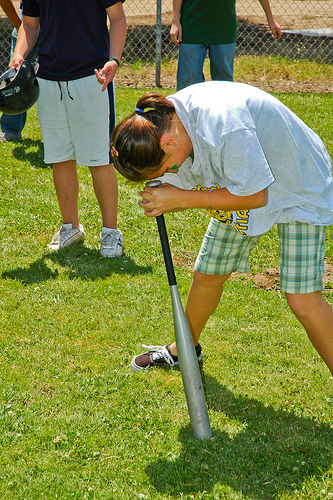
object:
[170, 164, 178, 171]
paint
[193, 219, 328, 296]
shorts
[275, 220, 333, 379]
legs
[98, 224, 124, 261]
foot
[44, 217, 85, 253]
foot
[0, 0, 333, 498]
ground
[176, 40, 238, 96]
jeans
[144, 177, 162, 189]
silver handle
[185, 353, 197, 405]
metal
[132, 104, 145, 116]
blue band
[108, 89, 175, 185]
hair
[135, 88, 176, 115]
ponytail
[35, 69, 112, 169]
white shorts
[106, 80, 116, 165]
navy stripe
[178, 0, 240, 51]
shirt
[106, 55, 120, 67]
black band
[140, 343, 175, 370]
shoe laces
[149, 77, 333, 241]
tee shirt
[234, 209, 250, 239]
writing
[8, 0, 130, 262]
man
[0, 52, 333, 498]
grass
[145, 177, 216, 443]
bat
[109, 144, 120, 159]
barette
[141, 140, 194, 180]
face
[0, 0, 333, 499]
field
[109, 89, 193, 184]
head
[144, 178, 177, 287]
handle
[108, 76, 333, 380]
woman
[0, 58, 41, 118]
baseball helmet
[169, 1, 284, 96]
man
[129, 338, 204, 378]
shoe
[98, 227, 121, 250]
laces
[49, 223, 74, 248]
laces